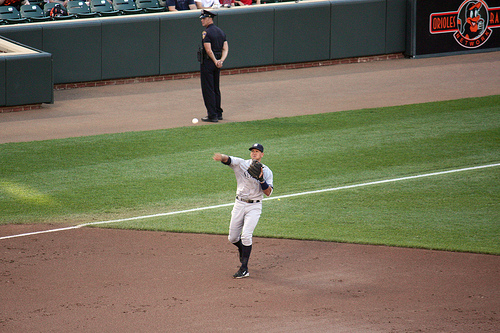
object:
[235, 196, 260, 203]
belt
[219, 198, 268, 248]
stop sign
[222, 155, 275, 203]
shirt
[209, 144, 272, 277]
man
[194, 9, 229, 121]
man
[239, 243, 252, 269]
socks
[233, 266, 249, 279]
shoe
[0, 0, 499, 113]
fence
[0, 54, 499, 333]
foul ground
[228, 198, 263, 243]
pants